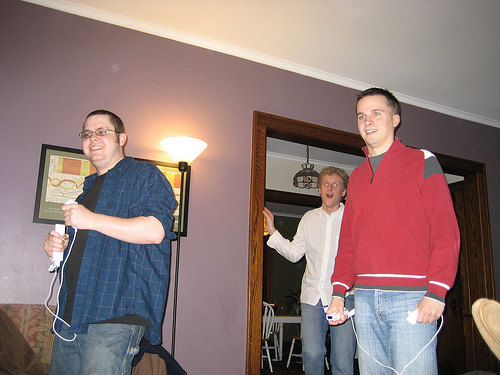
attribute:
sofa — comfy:
[0, 294, 190, 371]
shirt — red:
[327, 135, 466, 306]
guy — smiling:
[48, 109, 179, 374]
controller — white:
[54, 223, 65, 268]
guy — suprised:
[326, 88, 460, 373]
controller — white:
[328, 309, 352, 324]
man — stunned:
[263, 165, 355, 373]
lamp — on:
[165, 135, 209, 364]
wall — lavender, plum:
[1, 0, 266, 373]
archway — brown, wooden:
[248, 108, 494, 374]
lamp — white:
[295, 142, 320, 192]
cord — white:
[45, 227, 79, 341]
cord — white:
[347, 312, 444, 374]